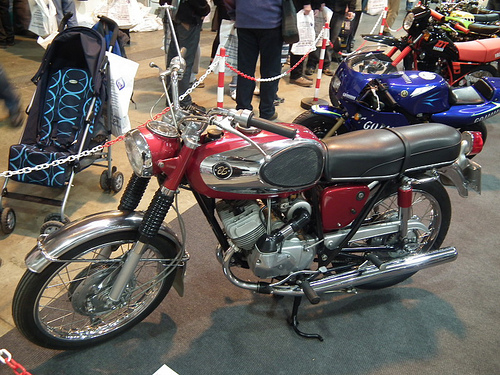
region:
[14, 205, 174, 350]
front wheel of motorcycle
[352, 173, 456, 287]
rear wheel of motorcycle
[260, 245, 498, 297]
exhaust on side of motorcycle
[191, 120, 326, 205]
gas tank on motorcycle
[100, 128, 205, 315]
front shock on motorcycle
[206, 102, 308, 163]
handle bar on motorcycle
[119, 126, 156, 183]
headlight on front of motorcycle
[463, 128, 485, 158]
tail light on motorcycle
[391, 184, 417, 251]
rear shock on motorcycle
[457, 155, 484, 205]
license plate on motorcycle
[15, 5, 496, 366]
gray carpeting under display of motorcycles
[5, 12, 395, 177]
red and white chain between red and white poles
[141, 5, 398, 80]
people standing on far side of chain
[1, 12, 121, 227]
baby stroller with blue intertwined circles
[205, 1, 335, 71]
people holding white plastic tote bags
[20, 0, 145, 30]
display of bags with red or blue writing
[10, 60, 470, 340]
red motorcycle with handlebar outside of chain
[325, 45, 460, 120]
blue vehicle with curved design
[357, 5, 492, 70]
black and orange motorcycle with long seat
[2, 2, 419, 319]
wooden floor under vistors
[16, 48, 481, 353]
red motorcycle in front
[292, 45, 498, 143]
the blue mortorcyle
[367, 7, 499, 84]
a red and black motorcycle with a red DT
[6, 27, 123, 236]
a black and blue baby stroller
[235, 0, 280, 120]
person with black pants and blue shirt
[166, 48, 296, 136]
red motorcycle's handlebars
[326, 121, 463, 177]
a red motorcycle's black leather seat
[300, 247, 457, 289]
chrome tailpipe on red bike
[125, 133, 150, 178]
the red motorcycle's headlight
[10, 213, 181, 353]
the red motorcycle's front wheel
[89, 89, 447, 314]
a motorcycle is on display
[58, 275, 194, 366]
the wheels are chrome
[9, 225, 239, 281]
silver covers the tire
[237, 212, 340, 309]
the engine is silver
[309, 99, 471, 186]
the seat is made of leather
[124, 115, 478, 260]
the bike is made of red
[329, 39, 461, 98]
a motorcycle is blue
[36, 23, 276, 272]
a baby stroller is blue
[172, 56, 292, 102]
the pole is red and white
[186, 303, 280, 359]
the ground is gray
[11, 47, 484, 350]
a red and grey motorcycle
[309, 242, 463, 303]
the exhaust pipe on a motorcycle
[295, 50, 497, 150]
a blue motorcycle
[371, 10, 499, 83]
a red and black motorcycle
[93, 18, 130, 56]
a blue and black backpack on a stroller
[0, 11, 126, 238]
a black and blue stroller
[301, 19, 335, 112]
a red and white striped pole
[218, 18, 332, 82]
a red and white chain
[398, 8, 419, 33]
the headlight of a motorcycle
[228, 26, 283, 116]
black pants on a person